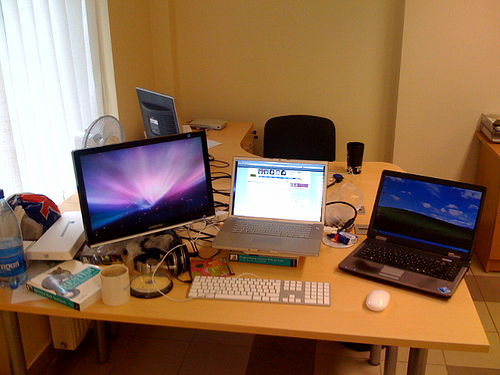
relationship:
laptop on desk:
[218, 154, 323, 262] [60, 133, 470, 296]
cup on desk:
[343, 135, 365, 177] [60, 133, 470, 296]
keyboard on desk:
[183, 269, 342, 309] [60, 133, 470, 296]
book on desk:
[38, 263, 105, 320] [60, 133, 470, 296]